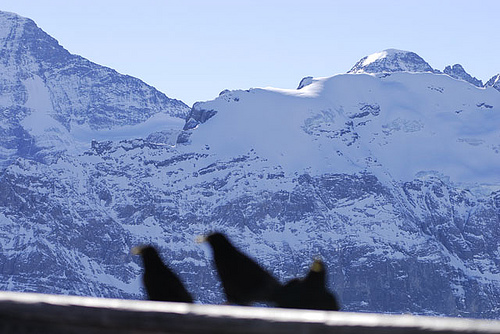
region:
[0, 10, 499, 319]
a distant mountain range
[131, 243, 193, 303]
a black bird with yellow beak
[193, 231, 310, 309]
a black bird with yellow beak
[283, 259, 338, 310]
a black bird with yellow beak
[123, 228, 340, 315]
group of black birds perched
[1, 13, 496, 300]
large snowy mountains in background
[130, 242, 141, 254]
beak of bird to left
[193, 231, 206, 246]
beak of bird in middle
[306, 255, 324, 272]
beak of bird to the right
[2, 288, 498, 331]
wood railing that birds are perched on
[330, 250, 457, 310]
lower elevation part of mountain with less snow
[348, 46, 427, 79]
peak of mountain to right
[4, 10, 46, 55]
Peak of mountain to left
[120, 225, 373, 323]
three black birds out of focus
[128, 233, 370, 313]
three black birds looking to the left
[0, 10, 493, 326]
snow covered mountains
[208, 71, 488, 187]
powered snow on the side of a mountain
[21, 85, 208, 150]
valley in between moutains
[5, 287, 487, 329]
railing from the balcony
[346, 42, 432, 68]
peak of a moutnain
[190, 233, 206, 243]
beak of the middle bird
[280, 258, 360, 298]
bird looking toward the camera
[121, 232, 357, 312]
three black birds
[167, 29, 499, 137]
The very top of a mountain.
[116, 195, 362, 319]
Three black birds.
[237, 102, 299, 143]
Snow on a mountain.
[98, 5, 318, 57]
A cloudy daytime sky.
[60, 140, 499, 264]
Cliff of a mountain.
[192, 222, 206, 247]
Yellow beak of a bird.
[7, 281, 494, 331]
Metal railing viewing mountains.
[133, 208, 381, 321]
Birds sitting on a railing.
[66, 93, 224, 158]
Slope heading down a mountain.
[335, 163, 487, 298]
Rocks on the side of a cliff.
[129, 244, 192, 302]
A black bird to the left of another.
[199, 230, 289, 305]
Biggest black bird.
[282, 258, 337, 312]
Lowest widest bird down.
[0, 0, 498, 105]
A baby blue sky.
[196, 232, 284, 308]
Largest black bird.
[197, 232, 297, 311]
Largest black bird with yellow beak.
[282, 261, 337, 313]
Black bird facing the camera.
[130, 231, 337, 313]
Three black birds with yellow beaks.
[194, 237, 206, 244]
Yellow beak on the largest black bird.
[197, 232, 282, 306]
Black bird that is the biggest with yellow beak.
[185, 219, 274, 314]
black bird on gray wall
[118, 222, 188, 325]
An animal in a field.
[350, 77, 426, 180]
Some snow on a mountain.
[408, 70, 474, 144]
Some snow on a mountain.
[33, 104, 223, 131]
Some snow on a mountain.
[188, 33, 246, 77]
a view of sky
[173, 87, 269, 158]
a view of snow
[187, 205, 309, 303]
a view of people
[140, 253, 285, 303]
a group near the snow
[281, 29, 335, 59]
a view of clouds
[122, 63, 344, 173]
a view of mountains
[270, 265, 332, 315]
A black bird close up.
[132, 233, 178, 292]
A black bird close up.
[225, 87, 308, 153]
Snow on a big mountain.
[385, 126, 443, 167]
Snow on a big mountain.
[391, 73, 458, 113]
Snow on a big mountain.